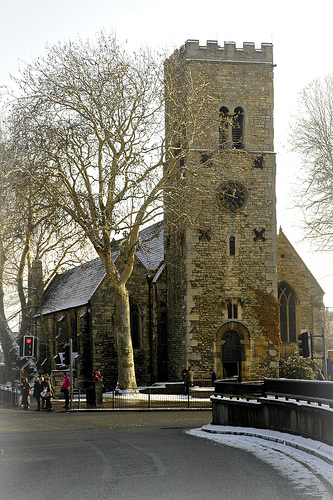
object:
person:
[43, 373, 54, 411]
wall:
[182, 40, 278, 371]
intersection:
[1, 404, 332, 498]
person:
[185, 366, 194, 388]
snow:
[192, 387, 330, 488]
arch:
[215, 319, 251, 339]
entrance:
[215, 321, 252, 380]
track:
[80, 403, 239, 490]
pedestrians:
[15, 363, 101, 411]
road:
[0, 406, 331, 498]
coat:
[62, 376, 71, 389]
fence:
[77, 382, 212, 408]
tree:
[5, 24, 181, 391]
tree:
[288, 67, 333, 254]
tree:
[0, 56, 54, 361]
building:
[165, 39, 282, 386]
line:
[109, 433, 167, 473]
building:
[30, 247, 155, 396]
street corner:
[96, 406, 213, 439]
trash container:
[86, 381, 105, 408]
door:
[221, 330, 244, 380]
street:
[0, 407, 330, 498]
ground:
[3, 436, 332, 499]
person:
[182, 364, 194, 395]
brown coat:
[183, 370, 194, 382]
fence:
[210, 378, 333, 445]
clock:
[218, 179, 248, 211]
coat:
[211, 372, 217, 386]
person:
[210, 369, 217, 386]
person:
[33, 377, 42, 412]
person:
[17, 377, 30, 410]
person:
[93, 371, 104, 388]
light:
[22, 335, 34, 357]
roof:
[33, 246, 148, 317]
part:
[145, 454, 174, 478]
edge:
[45, 415, 198, 427]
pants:
[63, 389, 69, 405]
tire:
[259, 444, 331, 500]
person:
[61, 372, 71, 408]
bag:
[46, 390, 53, 398]